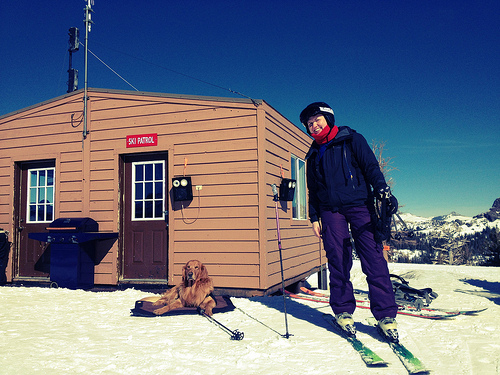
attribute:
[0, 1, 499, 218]
sky — blue, clear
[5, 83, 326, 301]
building — brown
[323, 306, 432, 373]
skis — green, long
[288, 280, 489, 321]
skis — purple, long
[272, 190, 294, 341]
ski pole — pink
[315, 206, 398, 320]
pants — purple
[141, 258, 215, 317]
dog — laying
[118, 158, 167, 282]
door — brown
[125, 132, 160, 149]
sign — red, white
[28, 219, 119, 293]
grill — blue, black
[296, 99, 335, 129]
helmet — black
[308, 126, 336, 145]
scarf — red